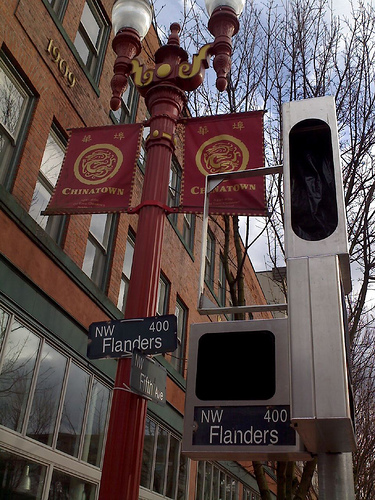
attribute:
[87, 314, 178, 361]
street sign — blue, dark blue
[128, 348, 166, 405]
street sign — blue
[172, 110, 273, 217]
flag — red, gold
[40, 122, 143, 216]
flag — red, gold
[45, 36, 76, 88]
numbers — gold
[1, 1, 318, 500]
building — brick red, tall, brick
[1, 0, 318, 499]
wood trim — green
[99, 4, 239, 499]
pole — red, metallic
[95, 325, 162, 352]
lettering — white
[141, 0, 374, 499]
tree branches — bare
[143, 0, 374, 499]
tree — bare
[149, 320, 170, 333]
400 — white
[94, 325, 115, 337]
nw — white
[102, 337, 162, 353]
flanders — white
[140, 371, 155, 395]
fifth — white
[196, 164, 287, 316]
sign holder — empty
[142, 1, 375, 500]
trees — bare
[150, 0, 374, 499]
sky — cloudy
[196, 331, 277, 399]
cross walk signal — blank